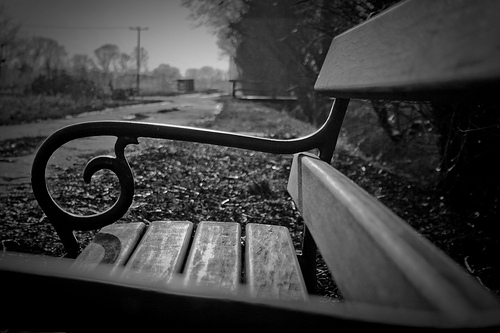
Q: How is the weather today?
A: It is cloudy.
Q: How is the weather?
A: It is cloudy.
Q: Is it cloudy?
A: Yes, it is cloudy.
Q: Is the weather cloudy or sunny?
A: It is cloudy.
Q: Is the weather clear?
A: No, it is cloudy.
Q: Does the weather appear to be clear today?
A: No, it is cloudy.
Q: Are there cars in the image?
A: No, there are no cars.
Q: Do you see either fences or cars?
A: No, there are no cars or fences.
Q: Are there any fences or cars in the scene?
A: No, there are no cars or fences.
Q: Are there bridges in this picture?
A: Yes, there is a bridge.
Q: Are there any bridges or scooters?
A: Yes, there is a bridge.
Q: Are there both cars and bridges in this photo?
A: No, there is a bridge but no cars.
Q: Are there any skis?
A: No, there are no skis.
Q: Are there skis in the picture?
A: No, there are no skis.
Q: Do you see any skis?
A: No, there are no skis.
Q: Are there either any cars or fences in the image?
A: No, there are no cars or fences.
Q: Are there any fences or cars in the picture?
A: No, there are no cars or fences.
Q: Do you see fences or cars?
A: No, there are no cars or fences.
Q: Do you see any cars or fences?
A: No, there are no cars or fences.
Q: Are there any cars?
A: No, there are no cars.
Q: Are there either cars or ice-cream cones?
A: No, there are no cars or ice-cream cones.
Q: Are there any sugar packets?
A: No, there are no sugar packets.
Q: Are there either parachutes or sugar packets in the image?
A: No, there are no sugar packets or parachutes.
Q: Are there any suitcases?
A: No, there are no suitcases.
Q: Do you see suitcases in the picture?
A: No, there are no suitcases.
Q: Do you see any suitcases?
A: No, there are no suitcases.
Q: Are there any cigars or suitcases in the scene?
A: No, there are no suitcases or cigars.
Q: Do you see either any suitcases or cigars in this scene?
A: No, there are no suitcases or cigars.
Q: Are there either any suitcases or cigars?
A: No, there are no suitcases or cigars.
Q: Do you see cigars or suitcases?
A: No, there are no suitcases or cigars.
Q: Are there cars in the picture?
A: No, there are no cars.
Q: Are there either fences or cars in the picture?
A: No, there are no cars or fences.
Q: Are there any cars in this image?
A: No, there are no cars.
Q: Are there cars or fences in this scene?
A: No, there are no cars or fences.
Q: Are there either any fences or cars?
A: No, there are no cars or fences.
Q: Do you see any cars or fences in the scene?
A: No, there are no cars or fences.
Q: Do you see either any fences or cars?
A: No, there are no cars or fences.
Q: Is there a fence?
A: No, there are no fences.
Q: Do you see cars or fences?
A: No, there are no fences or cars.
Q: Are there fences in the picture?
A: No, there are no fences.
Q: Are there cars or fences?
A: No, there are no fences or cars.